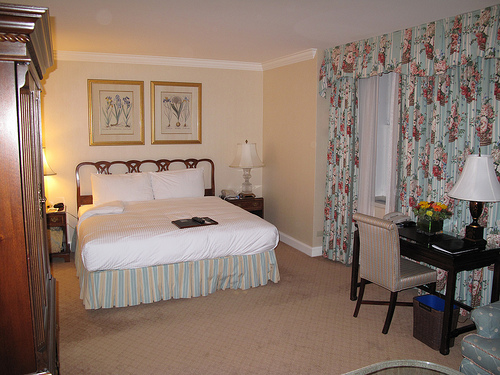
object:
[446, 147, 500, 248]
lamp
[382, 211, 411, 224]
phone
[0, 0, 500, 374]
bedroom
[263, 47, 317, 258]
wall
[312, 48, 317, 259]
edge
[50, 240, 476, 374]
floor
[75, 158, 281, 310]
bed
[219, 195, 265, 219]
stand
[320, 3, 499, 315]
curtain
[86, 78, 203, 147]
pictures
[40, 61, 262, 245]
wall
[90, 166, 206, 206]
pillows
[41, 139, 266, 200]
lamps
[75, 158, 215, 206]
headboard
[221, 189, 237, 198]
telephone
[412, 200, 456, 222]
flowers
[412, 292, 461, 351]
trash bin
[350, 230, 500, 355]
desk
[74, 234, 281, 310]
bed skirt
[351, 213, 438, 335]
chair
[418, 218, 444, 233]
pot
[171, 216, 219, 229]
book